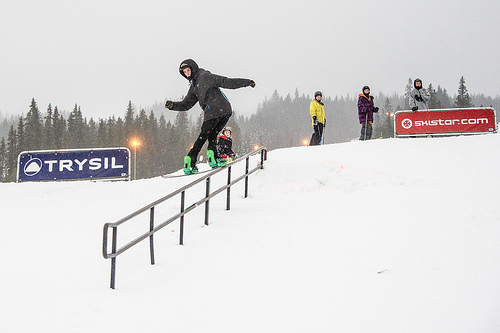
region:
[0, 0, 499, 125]
a large patch of gray sky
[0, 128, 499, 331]
a hill covered in snow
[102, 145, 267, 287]
a black metal railing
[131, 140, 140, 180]
a light pole in the distance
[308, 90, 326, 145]
person with a yellow jacket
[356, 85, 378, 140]
a person standing with ski poles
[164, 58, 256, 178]
a person snowboarding on the railing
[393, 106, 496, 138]
a red advertising sign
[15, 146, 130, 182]
a blue advertising sign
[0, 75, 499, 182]
a large forested area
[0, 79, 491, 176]
a bunch of pines in the back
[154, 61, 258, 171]
woman wearing black jacket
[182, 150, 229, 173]
light green ski shoes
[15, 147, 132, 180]
purple and white signboard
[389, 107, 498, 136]
red and hwite signboard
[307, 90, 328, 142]
man wearing yellow jacket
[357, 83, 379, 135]
woman wearing orange and purple jacket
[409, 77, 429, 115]
man wearing gray jacket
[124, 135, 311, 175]
three lampposts in the back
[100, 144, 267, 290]
gray metal banisters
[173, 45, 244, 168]
person doing trick on railing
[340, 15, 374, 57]
white clouds in blue sky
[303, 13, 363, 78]
white clouds in blue sky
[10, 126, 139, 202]
blue sign with white writing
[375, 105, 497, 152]
red sign with white writing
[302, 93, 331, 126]
person wearing yellow jacket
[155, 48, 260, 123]
person wear grey jacket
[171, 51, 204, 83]
person has hood on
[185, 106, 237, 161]
person wearing black pants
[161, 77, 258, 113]
person wearing black gloves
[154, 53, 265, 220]
person doing trick on rail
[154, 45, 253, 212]
person using snow board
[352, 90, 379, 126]
person wearing purple jacket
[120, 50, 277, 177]
person performing snowboard trick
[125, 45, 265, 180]
person on a snowboard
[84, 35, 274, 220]
person sliding down rail on snowboard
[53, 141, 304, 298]
metal rail for performing tricks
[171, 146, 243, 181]
neon green boots on snowboard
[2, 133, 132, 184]
blue sign on top of hill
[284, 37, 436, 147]
people watching snowboarder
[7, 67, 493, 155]
forest at the top of the hill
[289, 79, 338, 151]
person standing in a yellow jacket